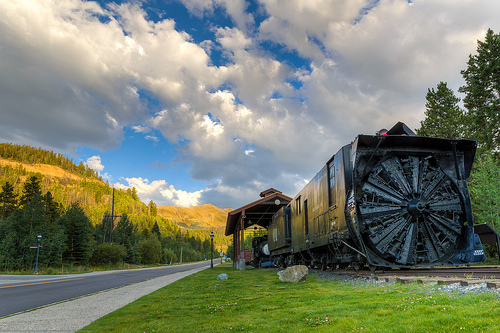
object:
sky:
[0, 0, 499, 211]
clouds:
[0, 0, 159, 163]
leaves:
[456, 28, 499, 152]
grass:
[74, 258, 500, 333]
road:
[0, 244, 220, 315]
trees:
[50, 201, 99, 263]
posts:
[210, 231, 214, 271]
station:
[225, 184, 295, 274]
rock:
[273, 266, 310, 283]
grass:
[83, 259, 499, 333]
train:
[261, 122, 491, 272]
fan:
[358, 153, 465, 269]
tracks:
[347, 258, 365, 271]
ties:
[344, 273, 500, 289]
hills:
[0, 142, 239, 261]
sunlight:
[0, 145, 279, 258]